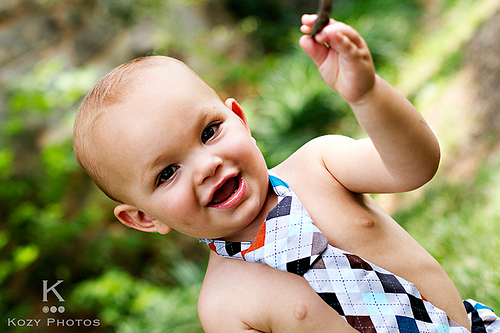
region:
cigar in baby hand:
[298, 1, 345, 44]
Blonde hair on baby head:
[81, 79, 125, 108]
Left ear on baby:
[101, 201, 178, 243]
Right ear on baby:
[224, 83, 265, 136]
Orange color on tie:
[233, 220, 271, 260]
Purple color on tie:
[263, 193, 301, 219]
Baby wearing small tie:
[210, 209, 440, 326]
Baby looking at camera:
[66, 72, 341, 327]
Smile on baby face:
[173, 147, 278, 217]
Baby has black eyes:
[124, 106, 239, 195]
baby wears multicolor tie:
[196, 179, 400, 329]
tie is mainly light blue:
[218, 206, 437, 330]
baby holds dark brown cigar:
[280, 19, 379, 94]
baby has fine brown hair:
[20, 65, 187, 153]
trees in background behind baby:
[2, 62, 181, 322]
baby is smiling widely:
[150, 133, 272, 235]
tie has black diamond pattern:
[267, 220, 424, 330]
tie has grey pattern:
[180, 169, 442, 331]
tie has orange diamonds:
[209, 219, 388, 308]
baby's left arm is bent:
[261, 9, 468, 196]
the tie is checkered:
[360, 287, 377, 308]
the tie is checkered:
[349, 273, 362, 300]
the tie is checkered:
[311, 275, 350, 314]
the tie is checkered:
[347, 280, 369, 330]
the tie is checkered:
[327, 281, 344, 318]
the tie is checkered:
[342, 273, 357, 303]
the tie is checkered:
[328, 301, 370, 331]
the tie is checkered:
[345, 300, 382, 325]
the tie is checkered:
[345, 295, 358, 322]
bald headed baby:
[49, 12, 499, 329]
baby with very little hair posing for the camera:
[69, 7, 495, 332]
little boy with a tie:
[57, 12, 491, 331]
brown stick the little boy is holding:
[302, 0, 342, 38]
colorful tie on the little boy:
[197, 167, 484, 331]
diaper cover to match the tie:
[464, 289, 498, 329]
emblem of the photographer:
[37, 274, 69, 312]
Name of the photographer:
[5, 309, 103, 331]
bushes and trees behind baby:
[22, 8, 255, 49]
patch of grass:
[452, 180, 497, 273]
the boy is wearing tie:
[345, 285, 359, 323]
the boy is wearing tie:
[353, 278, 365, 310]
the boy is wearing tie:
[347, 298, 360, 318]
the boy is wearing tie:
[332, 288, 344, 310]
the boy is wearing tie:
[336, 260, 353, 300]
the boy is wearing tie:
[324, 288, 343, 302]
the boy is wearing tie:
[341, 270, 361, 312]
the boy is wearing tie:
[309, 286, 326, 301]